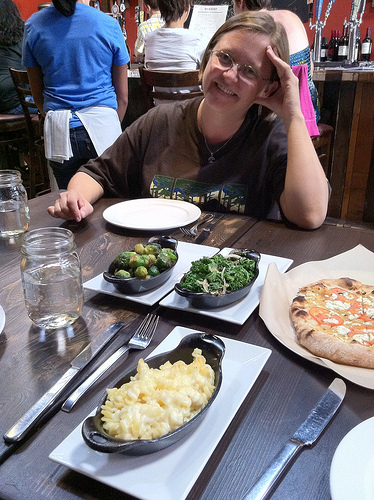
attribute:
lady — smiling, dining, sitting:
[48, 12, 328, 230]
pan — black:
[84, 332, 226, 457]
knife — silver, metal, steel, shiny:
[243, 377, 346, 499]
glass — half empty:
[21, 227, 84, 331]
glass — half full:
[1, 169, 28, 233]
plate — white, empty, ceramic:
[105, 195, 200, 229]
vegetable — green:
[184, 256, 257, 296]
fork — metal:
[63, 311, 158, 411]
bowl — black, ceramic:
[104, 234, 179, 292]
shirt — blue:
[23, 4, 131, 128]